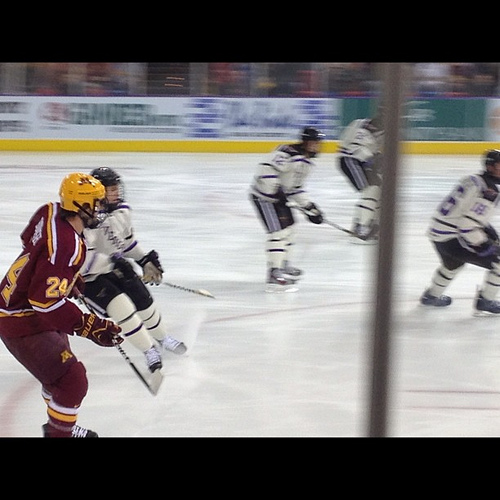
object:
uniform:
[0, 202, 88, 429]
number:
[46, 277, 68, 297]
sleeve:
[26, 250, 86, 336]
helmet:
[58, 172, 107, 213]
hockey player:
[0, 173, 123, 436]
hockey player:
[248, 127, 324, 295]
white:
[286, 166, 294, 185]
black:
[0, 438, 500, 500]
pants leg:
[0, 330, 87, 427]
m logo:
[61, 350, 73, 364]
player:
[419, 150, 499, 318]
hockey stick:
[286, 202, 379, 243]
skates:
[420, 289, 451, 306]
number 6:
[355, 132, 368, 140]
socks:
[267, 252, 284, 268]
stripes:
[266, 248, 285, 253]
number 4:
[2, 254, 32, 306]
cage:
[83, 197, 108, 228]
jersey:
[0, 202, 88, 333]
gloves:
[301, 202, 323, 225]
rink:
[0, 139, 500, 215]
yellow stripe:
[0, 139, 500, 154]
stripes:
[124, 323, 144, 338]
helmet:
[300, 126, 327, 141]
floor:
[0, 155, 500, 438]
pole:
[368, 63, 403, 437]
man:
[245, 125, 325, 294]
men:
[334, 104, 390, 245]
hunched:
[248, 167, 290, 205]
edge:
[0, 435, 500, 439]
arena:
[0, 152, 500, 441]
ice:
[403, 379, 498, 399]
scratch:
[198, 295, 477, 326]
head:
[59, 173, 102, 229]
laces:
[273, 268, 282, 278]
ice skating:
[264, 267, 300, 295]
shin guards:
[107, 292, 137, 323]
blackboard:
[0, 98, 500, 140]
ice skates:
[154, 334, 188, 355]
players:
[75, 167, 188, 376]